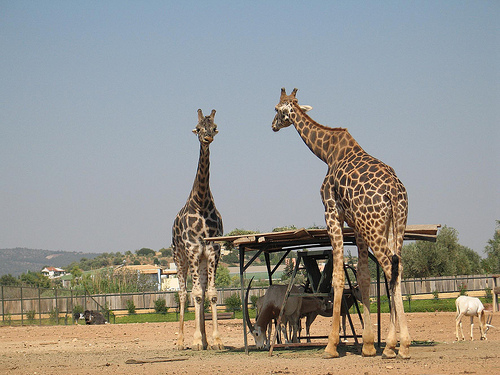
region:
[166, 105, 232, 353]
a curios giraffe looks at the camera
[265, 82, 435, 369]
a large giraffe looks away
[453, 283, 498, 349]
a white goat with long horns grazes nearby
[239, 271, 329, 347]
two goats stand between two giraffes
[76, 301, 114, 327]
a black cow laying on the ground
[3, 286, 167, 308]
a wooden fence surrounds the area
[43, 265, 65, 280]
a white house with a red roof sits in the distance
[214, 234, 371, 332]
a simple structure shades the animals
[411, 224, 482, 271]
trees tower over a fence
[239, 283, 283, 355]
a goats grazes on dried grass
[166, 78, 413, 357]
two brown and white giraffes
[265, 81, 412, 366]
brown, yellow, white and square spots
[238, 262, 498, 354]
white animals with antlers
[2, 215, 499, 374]
national preservation park site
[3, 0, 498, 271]
clear, blue cloudless sky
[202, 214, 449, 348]
wooden structure over animals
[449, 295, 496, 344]
white gazelle grazing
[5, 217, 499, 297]
green trees in the distance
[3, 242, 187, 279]
overcast green hills in background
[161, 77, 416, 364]
two giraffes facing each other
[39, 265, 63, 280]
this is a house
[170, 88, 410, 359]
these are wild animals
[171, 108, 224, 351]
this is a girraffe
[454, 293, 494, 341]
this is a gazelle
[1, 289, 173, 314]
this is a fence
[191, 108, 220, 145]
this is a girraffe's head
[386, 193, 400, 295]
this is a tail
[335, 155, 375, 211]
girrafe's spotted body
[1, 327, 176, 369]
this is the ground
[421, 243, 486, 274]
this are green trees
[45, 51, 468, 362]
animals within an outdoor enclosure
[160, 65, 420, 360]
giraffe on right bending neck to look at other giraffe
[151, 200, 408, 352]
antelopes in the shade of a structure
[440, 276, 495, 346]
white antelope on its own looking for food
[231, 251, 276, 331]
long curved horn pointing upward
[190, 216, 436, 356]
boards placed on top of metal supports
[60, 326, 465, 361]
dry ground with pebbles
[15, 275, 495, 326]
wooden fence along edge of enclosure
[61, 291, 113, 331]
large animal resting on ground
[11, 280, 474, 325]
grass and bushes along the inside of fencing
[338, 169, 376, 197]
spots on a giraffe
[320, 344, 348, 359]
the hoof of a giraffe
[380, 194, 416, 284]
the tail of a giraffe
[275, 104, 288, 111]
the ear of a giraffe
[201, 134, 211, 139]
the nose of a giraffe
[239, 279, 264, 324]
the horn of an animal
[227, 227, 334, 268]
a wooden roof on a metal frame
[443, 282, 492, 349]
a ram eating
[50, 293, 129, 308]
a wooden fence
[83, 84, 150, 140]
clear blue sky